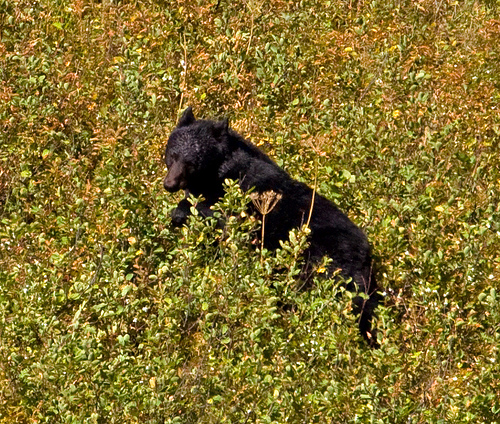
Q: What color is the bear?
A: Black.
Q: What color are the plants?
A: Green and yellow.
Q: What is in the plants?
A: The bear.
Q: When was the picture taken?
A: Daytime.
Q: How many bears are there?
A: One.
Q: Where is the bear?
A: In the plants.